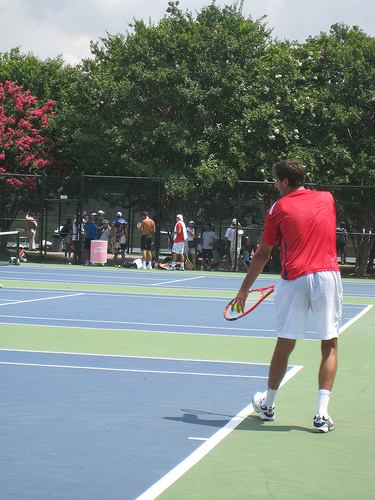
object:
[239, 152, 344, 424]
player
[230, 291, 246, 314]
hand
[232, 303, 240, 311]
ball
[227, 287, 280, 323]
racket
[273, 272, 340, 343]
shorts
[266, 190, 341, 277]
shirt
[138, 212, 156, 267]
man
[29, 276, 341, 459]
ground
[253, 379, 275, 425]
foot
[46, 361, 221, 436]
court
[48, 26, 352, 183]
trees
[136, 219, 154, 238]
torso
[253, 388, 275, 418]
shoe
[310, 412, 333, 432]
shoe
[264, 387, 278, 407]
sock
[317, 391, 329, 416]
sock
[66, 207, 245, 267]
spectators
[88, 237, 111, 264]
barrel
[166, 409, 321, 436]
shadow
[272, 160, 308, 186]
hair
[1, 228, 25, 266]
net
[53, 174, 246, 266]
fence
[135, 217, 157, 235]
chested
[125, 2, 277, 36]
tree top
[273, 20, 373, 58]
tree top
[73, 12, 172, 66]
tree top